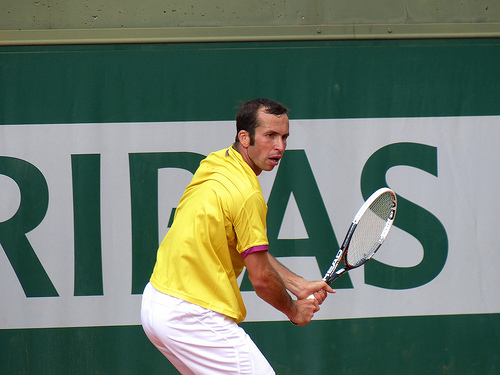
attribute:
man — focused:
[133, 94, 336, 374]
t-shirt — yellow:
[150, 152, 266, 319]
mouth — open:
[267, 151, 286, 163]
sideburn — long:
[247, 127, 260, 147]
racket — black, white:
[310, 178, 411, 301]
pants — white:
[138, 290, 273, 375]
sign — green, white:
[2, 120, 496, 326]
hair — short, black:
[224, 97, 288, 135]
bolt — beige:
[314, 28, 325, 35]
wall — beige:
[3, 2, 497, 371]